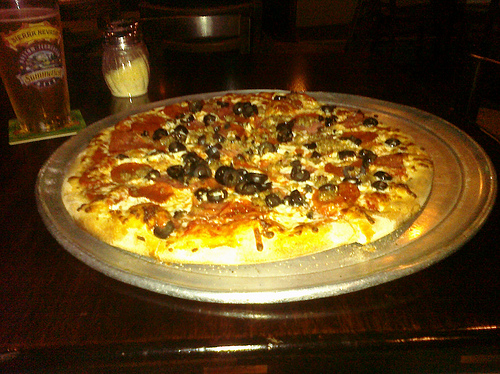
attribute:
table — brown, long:
[9, 40, 496, 369]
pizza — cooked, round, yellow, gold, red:
[81, 87, 387, 272]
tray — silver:
[41, 79, 479, 308]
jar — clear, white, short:
[92, 12, 169, 112]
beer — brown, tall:
[1, 1, 95, 137]